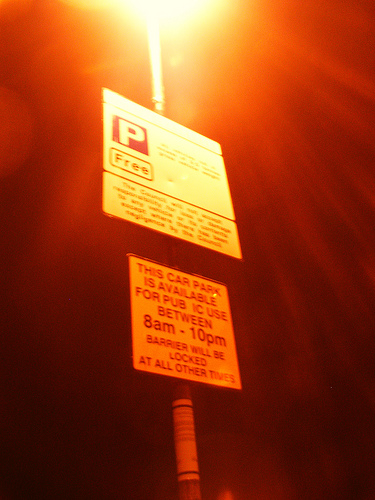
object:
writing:
[125, 250, 240, 391]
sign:
[125, 251, 241, 392]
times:
[142, 311, 227, 348]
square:
[101, 86, 243, 264]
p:
[111, 111, 149, 158]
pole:
[169, 378, 202, 500]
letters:
[213, 332, 227, 349]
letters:
[160, 322, 176, 338]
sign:
[99, 86, 249, 265]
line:
[101, 166, 237, 225]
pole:
[143, 11, 164, 113]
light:
[142, 9, 167, 109]